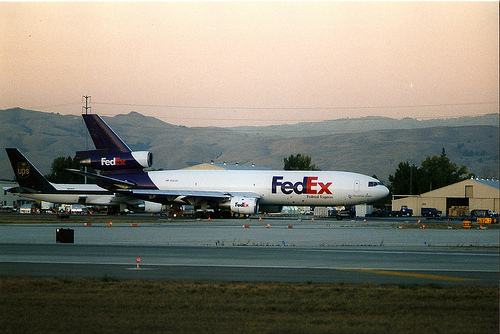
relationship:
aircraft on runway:
[55, 113, 392, 218] [0, 217, 498, 285]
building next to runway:
[391, 177, 498, 227] [3, 202, 497, 267]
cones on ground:
[149, 211, 336, 229] [190, 230, 339, 248]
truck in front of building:
[390, 204, 415, 219] [391, 174, 498, 221]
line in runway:
[363, 267, 481, 283] [0, 217, 498, 285]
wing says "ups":
[3, 143, 57, 199] [17, 166, 28, 174]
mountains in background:
[0, 104, 500, 181] [0, 6, 499, 218]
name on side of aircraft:
[262, 169, 335, 208] [80, 107, 391, 225]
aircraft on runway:
[27, 100, 434, 250] [0, 217, 498, 285]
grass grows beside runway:
[118, 263, 349, 321] [0, 214, 496, 280]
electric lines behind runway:
[63, 90, 498, 135] [2, 220, 499, 290]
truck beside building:
[387, 202, 419, 220] [388, 175, 497, 217]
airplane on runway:
[2, 146, 163, 213] [0, 217, 498, 285]